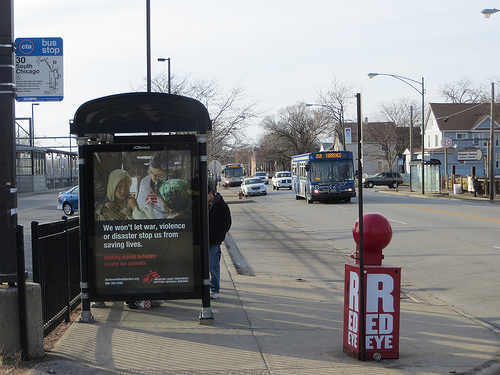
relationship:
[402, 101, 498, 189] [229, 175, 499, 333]
building near road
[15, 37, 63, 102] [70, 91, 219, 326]
sign for bus stop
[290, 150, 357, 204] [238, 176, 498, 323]
bus driving on road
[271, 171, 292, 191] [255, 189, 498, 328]
car driving on road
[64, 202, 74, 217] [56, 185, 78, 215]
tire on blue car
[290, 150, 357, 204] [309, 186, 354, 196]
bus has headlights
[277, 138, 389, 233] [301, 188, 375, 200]
bus has headlights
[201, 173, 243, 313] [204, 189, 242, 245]
person wearing jacket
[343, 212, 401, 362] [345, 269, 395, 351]
post with writing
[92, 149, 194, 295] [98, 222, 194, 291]
poster with writing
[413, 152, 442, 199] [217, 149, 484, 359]
bus stop on side of road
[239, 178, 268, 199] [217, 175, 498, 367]
car driving on road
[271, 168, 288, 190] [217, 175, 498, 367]
car driving on road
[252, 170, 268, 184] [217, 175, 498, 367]
car driving on road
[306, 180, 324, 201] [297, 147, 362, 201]
headlight of bus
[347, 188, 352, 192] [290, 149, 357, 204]
headlights of bus